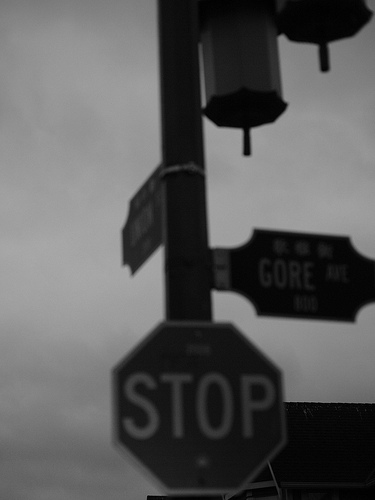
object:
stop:
[127, 371, 274, 447]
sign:
[105, 318, 293, 496]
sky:
[2, 3, 374, 499]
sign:
[229, 220, 374, 324]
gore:
[256, 253, 316, 296]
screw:
[193, 331, 206, 339]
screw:
[194, 455, 208, 470]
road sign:
[117, 171, 167, 270]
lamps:
[192, 2, 371, 156]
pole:
[157, 3, 213, 323]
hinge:
[210, 249, 233, 292]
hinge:
[160, 164, 204, 183]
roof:
[270, 392, 374, 486]